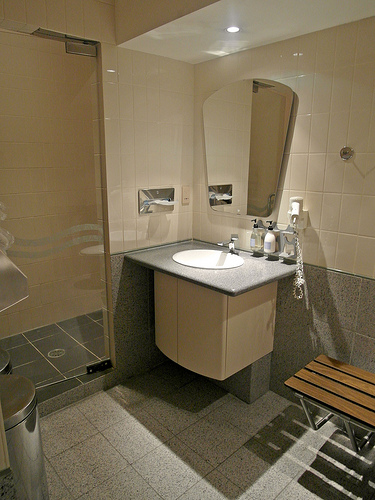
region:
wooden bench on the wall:
[253, 329, 372, 442]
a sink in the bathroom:
[145, 222, 291, 319]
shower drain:
[31, 340, 73, 365]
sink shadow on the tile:
[100, 361, 318, 498]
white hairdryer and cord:
[277, 195, 327, 316]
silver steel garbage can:
[0, 316, 74, 494]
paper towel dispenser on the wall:
[127, 181, 200, 230]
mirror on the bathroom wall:
[201, 64, 293, 233]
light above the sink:
[201, 18, 269, 53]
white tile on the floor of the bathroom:
[65, 410, 142, 488]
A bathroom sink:
[173, 236, 243, 275]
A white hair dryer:
[286, 196, 310, 233]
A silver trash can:
[0, 388, 48, 456]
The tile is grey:
[83, 405, 205, 472]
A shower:
[28, 317, 100, 367]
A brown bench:
[305, 350, 370, 414]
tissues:
[148, 194, 188, 209]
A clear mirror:
[211, 156, 276, 216]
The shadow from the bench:
[247, 416, 336, 482]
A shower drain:
[44, 347, 70, 358]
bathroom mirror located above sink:
[195, 87, 324, 216]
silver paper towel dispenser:
[134, 184, 194, 225]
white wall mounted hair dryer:
[286, 192, 325, 293]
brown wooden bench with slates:
[306, 354, 369, 426]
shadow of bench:
[275, 415, 340, 499]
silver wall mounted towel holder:
[326, 137, 373, 188]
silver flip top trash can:
[5, 372, 41, 498]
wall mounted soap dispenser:
[247, 217, 278, 262]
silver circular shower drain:
[43, 331, 86, 369]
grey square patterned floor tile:
[118, 410, 182, 498]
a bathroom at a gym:
[0, 0, 373, 498]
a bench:
[284, 349, 373, 452]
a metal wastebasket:
[0, 371, 45, 499]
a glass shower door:
[2, 39, 107, 375]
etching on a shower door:
[11, 223, 103, 258]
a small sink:
[124, 235, 297, 383]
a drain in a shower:
[47, 348, 67, 357]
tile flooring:
[51, 430, 319, 490]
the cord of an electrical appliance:
[293, 231, 303, 301]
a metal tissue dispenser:
[139, 188, 175, 213]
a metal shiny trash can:
[2, 362, 59, 490]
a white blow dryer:
[263, 181, 320, 245]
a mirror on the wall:
[319, 143, 367, 178]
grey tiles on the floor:
[68, 392, 288, 478]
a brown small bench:
[281, 338, 372, 421]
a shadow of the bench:
[248, 402, 370, 497]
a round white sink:
[174, 239, 242, 273]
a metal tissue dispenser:
[129, 184, 178, 220]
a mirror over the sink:
[176, 87, 288, 220]